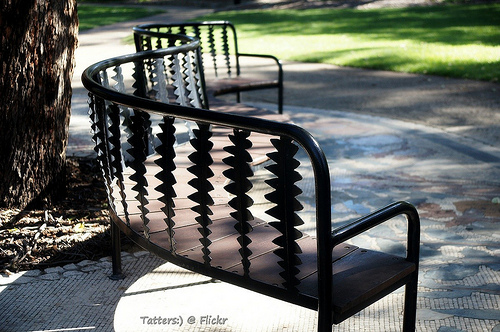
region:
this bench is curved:
[97, 18, 415, 293]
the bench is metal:
[85, 19, 446, 279]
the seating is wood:
[148, 186, 355, 297]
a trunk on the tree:
[5, 40, 81, 203]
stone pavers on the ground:
[303, 97, 498, 273]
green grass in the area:
[248, 14, 481, 88]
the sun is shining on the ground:
[95, 17, 497, 100]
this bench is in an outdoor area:
[21, 5, 497, 320]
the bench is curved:
[81, 20, 416, 330]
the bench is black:
[82, 18, 419, 330]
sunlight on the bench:
[110, 75, 350, 281]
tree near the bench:
[0, 2, 80, 207]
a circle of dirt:
[0, 155, 142, 273]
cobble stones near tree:
[0, 249, 148, 286]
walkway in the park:
[0, 6, 498, 330]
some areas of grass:
[77, 2, 499, 78]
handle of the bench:
[332, 202, 417, 263]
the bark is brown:
[0, 0, 77, 207]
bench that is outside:
[87, 59, 446, 326]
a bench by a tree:
[32, 14, 382, 329]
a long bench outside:
[53, 39, 475, 328]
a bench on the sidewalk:
[48, 14, 432, 324]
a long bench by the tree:
[111, 27, 461, 328]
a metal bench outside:
[50, 0, 442, 330]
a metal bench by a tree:
[43, 26, 413, 328]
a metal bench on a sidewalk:
[57, 9, 459, 324]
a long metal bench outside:
[75, 19, 367, 253]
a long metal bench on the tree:
[23, 29, 335, 317]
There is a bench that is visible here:
[254, 145, 277, 272]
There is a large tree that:
[18, 84, 35, 159]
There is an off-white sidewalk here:
[40, 287, 50, 329]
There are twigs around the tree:
[33, 220, 37, 240]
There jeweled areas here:
[360, 112, 377, 188]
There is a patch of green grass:
[415, 43, 425, 71]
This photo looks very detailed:
[116, 50, 316, 247]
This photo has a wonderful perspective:
[141, 61, 228, 312]